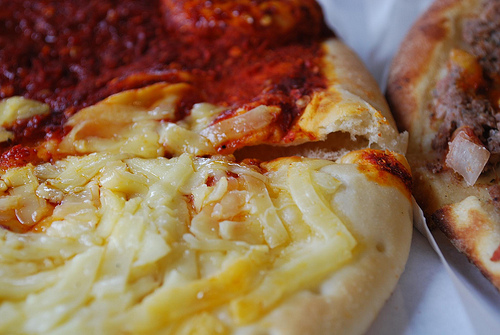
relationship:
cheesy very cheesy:
[0, 153, 292, 331] [51, 153, 292, 281]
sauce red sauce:
[0, 10, 271, 84] [0, 10, 271, 84]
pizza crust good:
[0, 13, 385, 298] [304, 168, 399, 268]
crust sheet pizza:
[300, 163, 412, 334] [0, 13, 385, 298]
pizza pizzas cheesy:
[0, 0, 384, 335] [0, 153, 292, 331]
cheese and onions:
[51, 153, 292, 281] [0, 161, 273, 282]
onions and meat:
[0, 161, 273, 282] [435, 79, 490, 121]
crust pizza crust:
[300, 163, 412, 334] [300, 163, 412, 320]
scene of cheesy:
[13, 4, 493, 334] [0, 153, 292, 331]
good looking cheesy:
[304, 168, 399, 268] [0, 153, 292, 331]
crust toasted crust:
[300, 163, 412, 334] [300, 163, 412, 320]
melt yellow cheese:
[51, 153, 292, 281] [0, 161, 273, 282]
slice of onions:
[51, 153, 292, 281] [0, 161, 273, 282]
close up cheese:
[277, 165, 332, 227] [51, 153, 292, 281]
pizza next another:
[0, 13, 385, 298] [268, 9, 483, 223]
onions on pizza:
[0, 161, 273, 282] [0, 13, 385, 298]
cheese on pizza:
[51, 153, 292, 281] [0, 13, 385, 298]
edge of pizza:
[300, 163, 412, 320] [0, 13, 385, 298]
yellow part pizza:
[51, 153, 292, 281] [0, 13, 385, 298]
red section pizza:
[0, 10, 271, 84] [0, 13, 385, 298]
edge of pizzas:
[368, 77, 414, 188] [295, 54, 447, 186]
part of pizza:
[179, 45, 389, 151] [0, 13, 385, 298]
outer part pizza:
[270, 199, 418, 334] [0, 13, 385, 298]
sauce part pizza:
[0, 10, 271, 84] [0, 13, 385, 298]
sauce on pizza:
[0, 10, 271, 84] [0, 13, 385, 298]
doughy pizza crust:
[276, 104, 398, 192] [300, 163, 412, 320]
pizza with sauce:
[0, 13, 385, 298] [0, 10, 271, 84]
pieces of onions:
[51, 153, 292, 281] [0, 161, 273, 282]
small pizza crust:
[276, 104, 398, 192] [300, 163, 412, 320]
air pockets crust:
[246, 100, 380, 168] [300, 163, 412, 320]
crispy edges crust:
[316, 142, 420, 213] [300, 163, 412, 320]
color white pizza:
[304, 168, 399, 268] [0, 13, 385, 298]